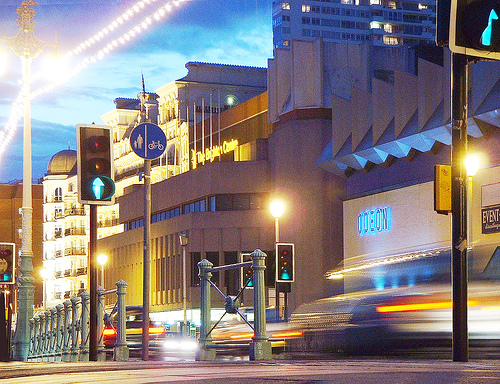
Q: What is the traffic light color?
A: Green.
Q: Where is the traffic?
A: On the street.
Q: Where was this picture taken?
A: In the city.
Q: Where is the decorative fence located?
A: Along street.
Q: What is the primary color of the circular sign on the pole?
A: Blue.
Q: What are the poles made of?
A: Metal.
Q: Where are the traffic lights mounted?
A: On poles.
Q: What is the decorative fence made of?
A: Metal.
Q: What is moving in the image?
A: Cars.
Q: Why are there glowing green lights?
A: Signal traffic to go.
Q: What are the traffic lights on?
A: Poles.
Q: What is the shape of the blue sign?
A: Round.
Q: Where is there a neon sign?
A: Face of building.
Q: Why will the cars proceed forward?
A: The light is green.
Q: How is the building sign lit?
A: With neon lights.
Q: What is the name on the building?
A: ODEON.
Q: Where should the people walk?
A: On the sidewalk.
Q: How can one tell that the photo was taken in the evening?
A: The lights are on.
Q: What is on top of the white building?
A: A dome.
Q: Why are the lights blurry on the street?
A: The car is moving.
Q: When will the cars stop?
A: The light turning red.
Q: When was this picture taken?
A: At night.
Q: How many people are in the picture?
A: None.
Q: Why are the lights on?
A: Its dark.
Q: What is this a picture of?
A: A city.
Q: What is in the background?
A: Buildings.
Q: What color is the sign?
A: Blue.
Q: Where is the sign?
A: On a pole.